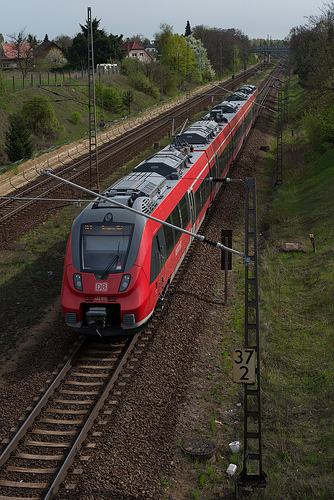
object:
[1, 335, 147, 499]
railroad track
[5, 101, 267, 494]
rocks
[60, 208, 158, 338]
end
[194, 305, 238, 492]
grass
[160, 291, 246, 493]
dirt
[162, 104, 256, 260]
windows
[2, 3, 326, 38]
skies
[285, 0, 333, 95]
trees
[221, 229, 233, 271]
sign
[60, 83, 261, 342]
cars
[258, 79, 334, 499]
grass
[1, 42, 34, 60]
roof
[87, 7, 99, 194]
structure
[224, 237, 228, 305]
pole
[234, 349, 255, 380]
372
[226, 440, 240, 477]
trash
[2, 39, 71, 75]
houses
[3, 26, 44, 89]
tree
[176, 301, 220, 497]
ground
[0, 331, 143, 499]
track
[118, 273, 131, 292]
headlight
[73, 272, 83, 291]
headlight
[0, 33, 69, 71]
building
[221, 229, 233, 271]
back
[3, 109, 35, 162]
foliage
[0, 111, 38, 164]
conifer tree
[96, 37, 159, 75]
houses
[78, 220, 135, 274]
trains windshield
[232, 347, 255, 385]
sign